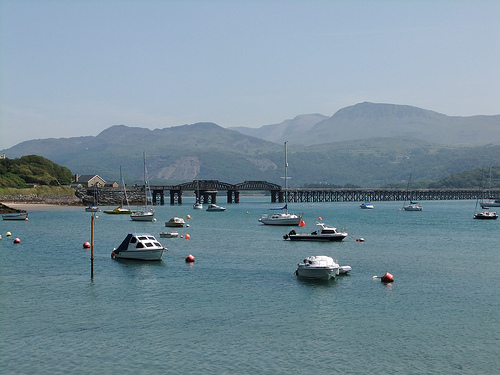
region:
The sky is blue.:
[1, 2, 498, 135]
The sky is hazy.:
[0, 0, 498, 141]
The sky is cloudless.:
[1, 2, 497, 129]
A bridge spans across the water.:
[100, 176, 497, 203]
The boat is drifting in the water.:
[106, 228, 166, 265]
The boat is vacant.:
[282, 250, 342, 288]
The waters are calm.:
[1, 193, 499, 373]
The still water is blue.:
[0, 196, 498, 373]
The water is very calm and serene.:
[0, 189, 499, 373]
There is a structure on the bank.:
[68, 170, 122, 191]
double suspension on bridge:
[171, 177, 283, 204]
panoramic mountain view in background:
[0, 95, 497, 172]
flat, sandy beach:
[0, 198, 87, 210]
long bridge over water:
[88, 180, 498, 205]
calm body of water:
[48, 287, 445, 367]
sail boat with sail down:
[258, 140, 303, 227]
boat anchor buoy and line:
[168, 249, 198, 269]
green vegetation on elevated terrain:
[1, 151, 72, 191]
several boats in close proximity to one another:
[74, 203, 496, 291]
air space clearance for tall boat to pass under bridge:
[242, 192, 272, 204]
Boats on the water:
[79, 199, 499, 339]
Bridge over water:
[89, 180, 498, 205]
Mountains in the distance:
[12, 97, 498, 179]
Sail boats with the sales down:
[83, 137, 499, 224]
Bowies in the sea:
[184, 210, 200, 272]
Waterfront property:
[73, 167, 122, 216]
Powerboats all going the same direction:
[107, 225, 414, 285]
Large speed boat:
[102, 227, 171, 274]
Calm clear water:
[1, 288, 498, 373]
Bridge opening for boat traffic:
[147, 173, 284, 215]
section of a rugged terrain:
[357, 125, 408, 147]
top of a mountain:
[349, 102, 371, 108]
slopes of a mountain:
[350, 110, 392, 138]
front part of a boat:
[323, 259, 332, 269]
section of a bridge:
[339, 187, 375, 202]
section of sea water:
[399, 302, 441, 340]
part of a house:
[90, 173, 95, 181]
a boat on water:
[296, 226, 336, 239]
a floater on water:
[383, 271, 390, 289]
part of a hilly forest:
[416, 120, 438, 160]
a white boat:
[275, 252, 347, 287]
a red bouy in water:
[374, 258, 399, 293]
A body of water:
[116, 285, 255, 355]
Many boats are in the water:
[42, 196, 246, 280]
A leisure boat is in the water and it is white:
[101, 227, 176, 317]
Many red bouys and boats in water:
[68, 208, 205, 270]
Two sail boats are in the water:
[108, 150, 157, 222]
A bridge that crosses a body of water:
[147, 180, 492, 203]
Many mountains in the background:
[80, 88, 499, 173]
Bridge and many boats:
[65, 161, 497, 288]